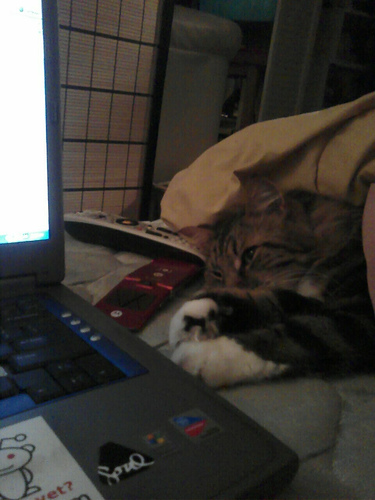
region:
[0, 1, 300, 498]
A computer by the cat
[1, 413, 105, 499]
A Reddit sticker on the computer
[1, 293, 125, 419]
A keyboard on the computer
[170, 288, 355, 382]
The front legs of the cat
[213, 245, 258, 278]
The eyes of the cat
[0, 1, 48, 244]
The screen on the laptop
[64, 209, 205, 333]
Remote controls on the bed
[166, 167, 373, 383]
A cat on the bed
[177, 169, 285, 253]
The ears of the cat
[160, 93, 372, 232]
A blanket on top of the cat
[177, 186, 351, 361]
striped cat laying down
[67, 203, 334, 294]
remote control next to cat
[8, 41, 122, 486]
lap top computer on a bed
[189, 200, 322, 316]
striped cat relaxing on mattress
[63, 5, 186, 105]
window screen in a room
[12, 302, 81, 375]
buttons on a computer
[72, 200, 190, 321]
two remotes on a bed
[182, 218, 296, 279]
cat with green eyes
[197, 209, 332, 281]
striped cat on a bed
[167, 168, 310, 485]
cat near a laptop computer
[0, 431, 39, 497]
this is the reddit logo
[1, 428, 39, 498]
the Reddit alien logo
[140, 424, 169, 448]
the Microsoft Windows logo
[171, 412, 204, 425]
this is the Intel logo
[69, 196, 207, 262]
this is a tv remote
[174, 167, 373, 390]
this is a cat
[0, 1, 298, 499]
this is a laptop computer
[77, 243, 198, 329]
this is a cell phone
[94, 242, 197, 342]
a pink flip phone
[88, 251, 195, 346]
this is a red Motorola Razr cell phone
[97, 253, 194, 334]
red motorola flip phone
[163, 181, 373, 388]
a cat on a bed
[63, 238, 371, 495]
gray mattress on a bed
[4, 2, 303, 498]
laptop computer on the bed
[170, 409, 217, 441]
intel sticker on the computer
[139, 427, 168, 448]
Windows sticker on the laptop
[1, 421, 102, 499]
Reddit sticker on laptop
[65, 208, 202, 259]
a television remote control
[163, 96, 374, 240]
a yellow colored blanket behind cat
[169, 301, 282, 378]
the cat's white paws